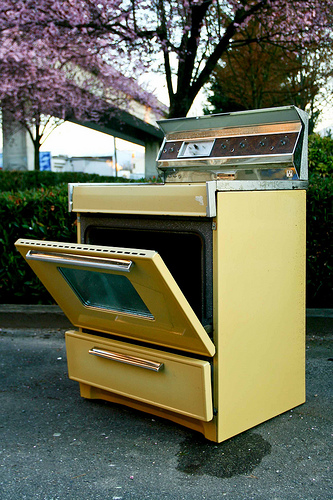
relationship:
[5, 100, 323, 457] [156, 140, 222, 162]
stove has knobs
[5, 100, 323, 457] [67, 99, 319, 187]
stove top silver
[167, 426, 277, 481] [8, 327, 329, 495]
liquid spilled on ground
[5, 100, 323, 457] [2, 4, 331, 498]
stove sitting outside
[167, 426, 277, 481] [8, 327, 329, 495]
spot on concrete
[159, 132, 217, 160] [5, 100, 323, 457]
dials on stove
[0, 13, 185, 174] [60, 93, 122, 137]
building has window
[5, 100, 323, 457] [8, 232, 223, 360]
stove has door open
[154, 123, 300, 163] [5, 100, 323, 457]
panel on stove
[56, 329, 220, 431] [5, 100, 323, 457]
storage draw on stove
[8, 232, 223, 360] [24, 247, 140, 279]
door has handle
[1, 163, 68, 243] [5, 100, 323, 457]
bushes behind stove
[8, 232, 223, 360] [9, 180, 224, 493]
oven in foreground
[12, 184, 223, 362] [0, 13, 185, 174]
oven outside house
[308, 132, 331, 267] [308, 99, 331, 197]
bush in background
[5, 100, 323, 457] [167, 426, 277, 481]
oven leaking water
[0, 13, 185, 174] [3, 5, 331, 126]
building in background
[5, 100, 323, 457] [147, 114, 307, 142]
stove has top light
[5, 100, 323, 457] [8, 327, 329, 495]
stove outside on grey pavement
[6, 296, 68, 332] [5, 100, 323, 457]
curb behind stove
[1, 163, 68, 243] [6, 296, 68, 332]
bushes behind curb